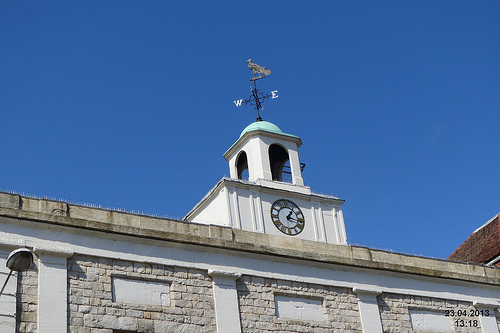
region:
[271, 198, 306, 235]
A clock on the tower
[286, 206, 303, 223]
The hands of the clock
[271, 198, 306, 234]
Roman numerals on the clock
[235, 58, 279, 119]
A directional sign above the building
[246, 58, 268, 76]
A metallic bird on the directional sign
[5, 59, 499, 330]
A building with a clocktower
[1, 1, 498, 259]
The sky above the building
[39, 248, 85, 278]
A shadow on the building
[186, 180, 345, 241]
A clock on the white wall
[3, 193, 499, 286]
The ledge of the building's roof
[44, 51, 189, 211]
a clear blue sky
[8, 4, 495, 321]
the sky is blue with a weather vaine attached to a cement building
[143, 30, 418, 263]
a clock witha blue sky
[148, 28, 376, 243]
a weather vaine with a blue sky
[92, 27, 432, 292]
the sky is blue with a weather vaine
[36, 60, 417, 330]
a clock with a blue sky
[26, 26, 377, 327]
a weather vain ontop of a building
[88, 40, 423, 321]
a weather vane ontop a cement building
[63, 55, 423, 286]
a blue sky with a concrete building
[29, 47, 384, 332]
a concrete building with a clear blue sky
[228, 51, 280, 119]
weather vane on top of the roof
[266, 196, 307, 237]
clock on the wall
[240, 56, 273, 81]
bird on the weather vane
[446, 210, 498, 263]
brown roof on the building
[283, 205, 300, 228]
hands on the clock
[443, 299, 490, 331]
time and date the photo was taken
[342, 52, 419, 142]
blue clear sunny sky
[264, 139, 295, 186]
window on the top of the building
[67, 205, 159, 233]
cement slab on the building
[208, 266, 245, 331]
white pillar on the building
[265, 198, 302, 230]
the black and white clock of a building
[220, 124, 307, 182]
the clock tower of a building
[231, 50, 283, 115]
the metal weather vane of the tower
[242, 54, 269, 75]
the metal bird on the weather vane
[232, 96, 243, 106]
the W of the weather vane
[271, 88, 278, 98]
the E of the weathervance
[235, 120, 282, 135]
the light green dome of the tower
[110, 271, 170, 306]
a white square on the building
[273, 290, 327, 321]
a white square on the building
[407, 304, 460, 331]
a white square on the building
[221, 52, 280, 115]
The weather vane is on top.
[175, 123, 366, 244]
The top is white.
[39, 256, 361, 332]
The building is brick.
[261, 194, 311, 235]
The face is white.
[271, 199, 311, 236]
The hands are black.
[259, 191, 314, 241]
The numbers are black.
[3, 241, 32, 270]
The light is off.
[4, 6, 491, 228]
The sky is clear blue.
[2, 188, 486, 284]
The gutters are tan.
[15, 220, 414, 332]
The building is white.